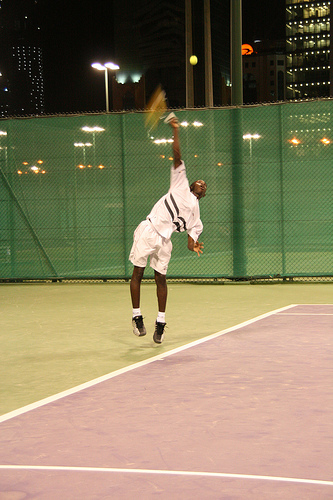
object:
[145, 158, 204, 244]
shirt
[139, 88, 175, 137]
racket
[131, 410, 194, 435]
part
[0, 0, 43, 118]
building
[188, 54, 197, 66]
ball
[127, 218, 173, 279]
white tennisuniform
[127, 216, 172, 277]
shorts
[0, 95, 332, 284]
fence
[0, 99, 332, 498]
court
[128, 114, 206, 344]
man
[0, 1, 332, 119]
sky